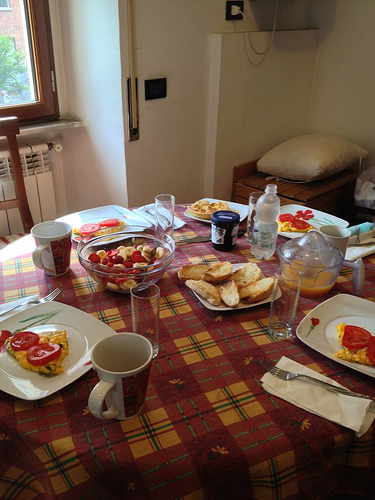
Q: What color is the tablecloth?
A: Red, yellow, and green.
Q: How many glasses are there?
A: Four.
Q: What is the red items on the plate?
A: Tomatoes.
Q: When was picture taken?
A: Daytime.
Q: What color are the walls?
A: White.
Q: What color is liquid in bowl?
A: Orange.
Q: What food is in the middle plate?
A: Bread.